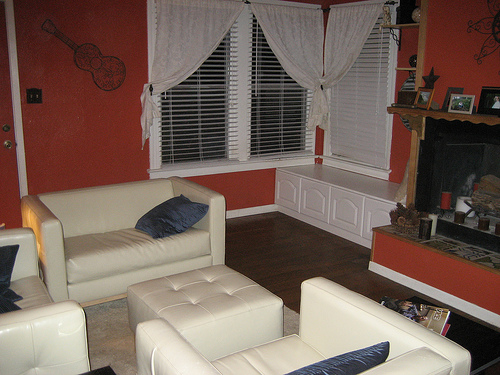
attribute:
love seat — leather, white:
[20, 177, 229, 305]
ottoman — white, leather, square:
[122, 262, 287, 361]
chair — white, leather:
[0, 226, 96, 373]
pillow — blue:
[0, 243, 26, 303]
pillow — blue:
[137, 188, 209, 242]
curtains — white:
[140, 1, 382, 166]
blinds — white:
[159, 10, 393, 167]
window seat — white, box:
[268, 157, 413, 247]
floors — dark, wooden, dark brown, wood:
[221, 208, 415, 309]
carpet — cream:
[84, 296, 153, 373]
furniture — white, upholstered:
[1, 172, 475, 373]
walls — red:
[0, 1, 495, 314]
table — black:
[385, 290, 498, 374]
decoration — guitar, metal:
[42, 16, 126, 90]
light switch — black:
[25, 88, 46, 106]